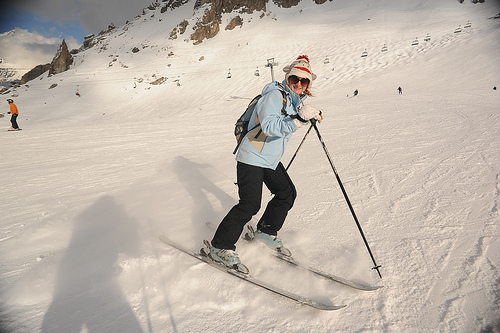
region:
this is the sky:
[6, 16, 28, 30]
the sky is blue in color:
[3, 14, 16, 25]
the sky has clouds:
[35, 3, 127, 21]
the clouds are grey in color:
[56, 2, 111, 32]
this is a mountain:
[76, 18, 492, 318]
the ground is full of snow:
[66, 210, 144, 267]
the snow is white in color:
[394, 207, 473, 293]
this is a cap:
[283, 57, 310, 74]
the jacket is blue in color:
[261, 98, 272, 111]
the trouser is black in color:
[240, 174, 253, 204]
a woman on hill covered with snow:
[86, 36, 453, 324]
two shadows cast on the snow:
[42, 148, 241, 331]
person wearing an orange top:
[1, 93, 24, 135]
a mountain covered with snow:
[20, 0, 497, 81]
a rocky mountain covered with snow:
[10, 0, 486, 66]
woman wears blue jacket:
[198, 49, 338, 280]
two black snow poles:
[291, 112, 396, 278]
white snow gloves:
[289, 98, 331, 137]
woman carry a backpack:
[213, 39, 342, 204]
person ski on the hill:
[3, 80, 31, 140]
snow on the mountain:
[36, 135, 198, 201]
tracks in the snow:
[109, 250, 181, 318]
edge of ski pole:
[363, 259, 397, 276]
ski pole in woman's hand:
[300, 102, 413, 293]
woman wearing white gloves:
[290, 100, 326, 127]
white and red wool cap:
[279, 52, 319, 80]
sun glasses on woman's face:
[273, 73, 315, 90]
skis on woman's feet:
[161, 223, 399, 325]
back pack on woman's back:
[215, 83, 285, 131]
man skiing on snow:
[4, 93, 34, 133]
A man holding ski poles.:
[154, 37, 401, 312]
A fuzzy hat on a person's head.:
[281, 48, 330, 79]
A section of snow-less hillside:
[189, 5, 229, 59]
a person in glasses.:
[284, 48, 326, 110]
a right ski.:
[156, 228, 350, 323]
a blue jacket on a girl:
[226, 88, 315, 177]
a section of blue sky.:
[4, 0, 91, 38]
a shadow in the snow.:
[40, 183, 168, 328]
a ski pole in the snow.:
[303, 103, 398, 294]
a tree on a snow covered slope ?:
[396, 73, 410, 95]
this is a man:
[197, 28, 367, 279]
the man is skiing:
[189, 55, 326, 283]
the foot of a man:
[196, 158, 267, 288]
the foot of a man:
[244, 156, 298, 260]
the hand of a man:
[249, 98, 321, 155]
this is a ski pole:
[300, 107, 405, 293]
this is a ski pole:
[276, 102, 326, 178]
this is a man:
[4, 90, 39, 138]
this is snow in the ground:
[139, 222, 209, 329]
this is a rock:
[46, 39, 89, 96]